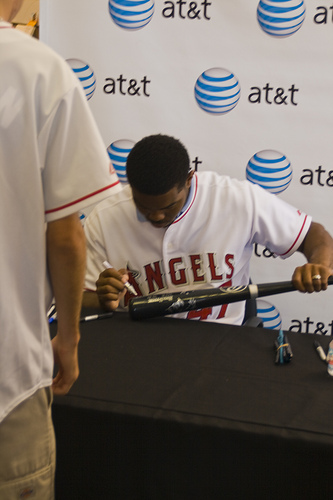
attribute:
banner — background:
[37, 0, 332, 338]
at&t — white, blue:
[103, 1, 218, 34]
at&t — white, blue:
[191, 67, 303, 118]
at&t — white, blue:
[52, 58, 152, 101]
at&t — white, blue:
[244, 147, 332, 198]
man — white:
[1, 14, 122, 499]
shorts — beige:
[5, 375, 69, 499]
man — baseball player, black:
[78, 133, 332, 329]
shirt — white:
[1, 19, 127, 427]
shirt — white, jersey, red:
[82, 170, 314, 329]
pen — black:
[310, 336, 328, 363]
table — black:
[48, 296, 333, 498]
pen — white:
[100, 254, 141, 297]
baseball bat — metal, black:
[126, 269, 333, 323]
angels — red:
[120, 250, 240, 310]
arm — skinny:
[43, 54, 92, 400]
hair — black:
[126, 132, 190, 191]